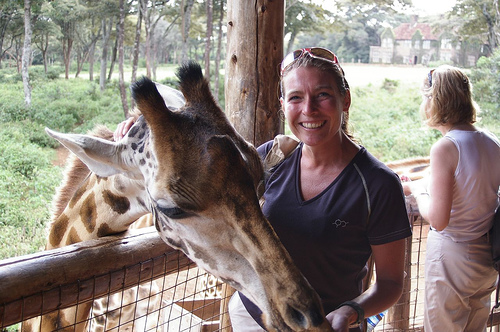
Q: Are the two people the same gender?
A: Yes, all the people are female.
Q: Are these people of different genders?
A: No, all the people are female.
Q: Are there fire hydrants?
A: No, there are no fire hydrants.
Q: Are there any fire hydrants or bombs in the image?
A: No, there are no fire hydrants or bombs.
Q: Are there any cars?
A: No, there are no cars.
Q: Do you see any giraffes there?
A: Yes, there is a giraffe.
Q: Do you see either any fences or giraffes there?
A: Yes, there is a giraffe.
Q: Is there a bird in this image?
A: No, there are no birds.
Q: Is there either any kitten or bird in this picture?
A: No, there are no birds or kittens.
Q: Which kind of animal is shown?
A: The animal is a giraffe.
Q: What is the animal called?
A: The animal is a giraffe.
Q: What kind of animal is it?
A: The animal is a giraffe.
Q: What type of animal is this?
A: This is a giraffe.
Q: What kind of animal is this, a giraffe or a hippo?
A: This is a giraffe.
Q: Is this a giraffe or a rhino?
A: This is a giraffe.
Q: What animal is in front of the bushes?
A: The giraffe is in front of the shrubs.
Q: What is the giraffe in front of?
A: The giraffe is in front of the bushes.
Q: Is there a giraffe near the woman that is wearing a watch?
A: Yes, there is a giraffe near the woman.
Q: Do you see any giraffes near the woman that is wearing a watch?
A: Yes, there is a giraffe near the woman.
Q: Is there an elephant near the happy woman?
A: No, there is a giraffe near the woman.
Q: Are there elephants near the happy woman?
A: No, there is a giraffe near the woman.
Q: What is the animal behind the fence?
A: The animal is a giraffe.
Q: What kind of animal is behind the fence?
A: The animal is a giraffe.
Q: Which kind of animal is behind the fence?
A: The animal is a giraffe.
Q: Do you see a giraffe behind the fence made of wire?
A: Yes, there is a giraffe behind the fence.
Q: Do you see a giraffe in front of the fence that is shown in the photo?
A: No, the giraffe is behind the fence.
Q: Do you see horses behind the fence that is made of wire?
A: No, there is a giraffe behind the fence.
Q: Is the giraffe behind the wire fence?
A: Yes, the giraffe is behind the fence.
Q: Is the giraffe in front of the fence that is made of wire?
A: No, the giraffe is behind the fence.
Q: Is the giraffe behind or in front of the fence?
A: The giraffe is behind the fence.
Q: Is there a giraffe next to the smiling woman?
A: Yes, there is a giraffe next to the woman.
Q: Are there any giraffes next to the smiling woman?
A: Yes, there is a giraffe next to the woman.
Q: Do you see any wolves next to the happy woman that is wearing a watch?
A: No, there is a giraffe next to the woman.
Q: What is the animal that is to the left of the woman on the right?
A: The animal is a giraffe.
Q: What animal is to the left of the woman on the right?
A: The animal is a giraffe.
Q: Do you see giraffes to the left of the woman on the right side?
A: Yes, there is a giraffe to the left of the woman.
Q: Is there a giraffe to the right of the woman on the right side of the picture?
A: No, the giraffe is to the left of the woman.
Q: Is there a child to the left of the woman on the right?
A: No, there is a giraffe to the left of the woman.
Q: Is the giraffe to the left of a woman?
A: Yes, the giraffe is to the left of a woman.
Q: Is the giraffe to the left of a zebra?
A: No, the giraffe is to the left of a woman.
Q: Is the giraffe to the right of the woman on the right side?
A: No, the giraffe is to the left of the woman.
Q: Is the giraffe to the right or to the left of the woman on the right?
A: The giraffe is to the left of the woman.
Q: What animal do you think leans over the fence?
A: The giraffe leans over the fence.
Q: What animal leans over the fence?
A: The giraffe leans over the fence.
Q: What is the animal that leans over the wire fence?
A: The animal is a giraffe.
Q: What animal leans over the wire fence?
A: The animal is a giraffe.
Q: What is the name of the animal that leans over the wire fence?
A: The animal is a giraffe.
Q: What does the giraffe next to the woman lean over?
A: The giraffe leans over the fence.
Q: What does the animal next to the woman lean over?
A: The giraffe leans over the fence.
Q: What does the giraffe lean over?
A: The giraffe leans over the fence.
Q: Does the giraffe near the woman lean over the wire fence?
A: Yes, the giraffe leans over the fence.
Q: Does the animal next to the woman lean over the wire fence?
A: Yes, the giraffe leans over the fence.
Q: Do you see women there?
A: Yes, there is a woman.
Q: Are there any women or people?
A: Yes, there is a woman.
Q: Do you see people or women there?
A: Yes, there is a woman.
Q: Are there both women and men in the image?
A: No, there is a woman but no men.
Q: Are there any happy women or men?
A: Yes, there is a happy woman.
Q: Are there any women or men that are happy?
A: Yes, the woman is happy.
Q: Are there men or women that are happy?
A: Yes, the woman is happy.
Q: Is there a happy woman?
A: Yes, there is a happy woman.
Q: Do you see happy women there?
A: Yes, there is a happy woman.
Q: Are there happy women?
A: Yes, there is a happy woman.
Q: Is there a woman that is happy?
A: Yes, there is a woman that is happy.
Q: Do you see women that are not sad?
A: Yes, there is a happy woman.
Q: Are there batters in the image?
A: No, there are no batters.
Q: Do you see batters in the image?
A: No, there are no batters.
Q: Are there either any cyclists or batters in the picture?
A: No, there are no batters or cyclists.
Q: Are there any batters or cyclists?
A: No, there are no batters or cyclists.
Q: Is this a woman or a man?
A: This is a woman.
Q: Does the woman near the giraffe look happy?
A: Yes, the woman is happy.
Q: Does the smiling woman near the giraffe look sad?
A: No, the woman is happy.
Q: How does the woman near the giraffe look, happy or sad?
A: The woman is happy.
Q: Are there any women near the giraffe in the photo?
A: Yes, there is a woman near the giraffe.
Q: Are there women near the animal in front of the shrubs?
A: Yes, there is a woman near the giraffe.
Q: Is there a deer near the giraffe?
A: No, there is a woman near the giraffe.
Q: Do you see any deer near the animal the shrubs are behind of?
A: No, there is a woman near the giraffe.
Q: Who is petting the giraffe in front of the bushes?
A: The woman is petting the giraffe.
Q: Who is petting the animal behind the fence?
A: The woman is petting the giraffe.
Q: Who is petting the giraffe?
A: The woman is petting the giraffe.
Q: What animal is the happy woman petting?
A: The woman is petting the giraffe.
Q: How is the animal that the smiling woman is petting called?
A: The animal is a giraffe.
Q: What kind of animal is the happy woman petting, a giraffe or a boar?
A: The woman is petting a giraffe.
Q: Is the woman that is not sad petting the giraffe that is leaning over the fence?
A: Yes, the woman is petting the giraffe.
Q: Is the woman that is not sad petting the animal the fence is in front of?
A: Yes, the woman is petting the giraffe.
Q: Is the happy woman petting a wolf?
A: No, the woman is petting the giraffe.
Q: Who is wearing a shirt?
A: The woman is wearing a shirt.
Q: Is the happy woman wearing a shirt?
A: Yes, the woman is wearing a shirt.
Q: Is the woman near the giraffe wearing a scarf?
A: No, the woman is wearing a shirt.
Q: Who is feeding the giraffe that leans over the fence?
A: The woman is feeding the giraffe.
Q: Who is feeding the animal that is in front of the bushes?
A: The woman is feeding the giraffe.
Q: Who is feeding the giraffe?
A: The woman is feeding the giraffe.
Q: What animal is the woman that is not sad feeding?
A: The woman is feeding the giraffe.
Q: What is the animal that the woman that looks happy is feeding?
A: The animal is a giraffe.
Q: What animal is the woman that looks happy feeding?
A: The woman is feeding the giraffe.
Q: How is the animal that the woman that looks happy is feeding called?
A: The animal is a giraffe.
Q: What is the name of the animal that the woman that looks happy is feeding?
A: The animal is a giraffe.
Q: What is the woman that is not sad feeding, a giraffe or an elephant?
A: The woman is feeding a giraffe.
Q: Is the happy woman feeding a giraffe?
A: Yes, the woman is feeding a giraffe.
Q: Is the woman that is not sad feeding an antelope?
A: No, the woman is feeding a giraffe.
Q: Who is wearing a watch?
A: The woman is wearing a watch.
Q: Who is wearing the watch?
A: The woman is wearing a watch.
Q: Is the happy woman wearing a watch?
A: Yes, the woman is wearing a watch.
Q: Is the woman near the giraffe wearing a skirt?
A: No, the woman is wearing a watch.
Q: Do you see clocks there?
A: No, there are no clocks.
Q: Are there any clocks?
A: No, there are no clocks.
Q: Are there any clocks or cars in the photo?
A: No, there are no clocks or cars.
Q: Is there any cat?
A: No, there are no cats.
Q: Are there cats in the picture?
A: No, there are no cats.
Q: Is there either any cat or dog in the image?
A: No, there are no cats or dogs.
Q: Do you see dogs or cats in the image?
A: No, there are no cats or dogs.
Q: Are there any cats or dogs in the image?
A: No, there are no cats or dogs.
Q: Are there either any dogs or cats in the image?
A: No, there are no cats or dogs.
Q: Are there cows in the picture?
A: No, there are no cows.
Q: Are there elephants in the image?
A: No, there are no elephants.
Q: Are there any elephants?
A: No, there are no elephants.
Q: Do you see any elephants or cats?
A: No, there are no elephants or cats.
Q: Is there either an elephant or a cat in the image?
A: No, there are no elephants or cats.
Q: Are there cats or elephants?
A: No, there are no elephants or cats.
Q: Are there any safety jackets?
A: No, there are no safety jackets.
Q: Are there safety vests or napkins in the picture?
A: No, there are no safety vests or napkins.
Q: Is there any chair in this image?
A: No, there are no chairs.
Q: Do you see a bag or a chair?
A: No, there are no chairs or bags.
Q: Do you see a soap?
A: No, there are no soaps.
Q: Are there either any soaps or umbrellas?
A: No, there are no soaps or umbrellas.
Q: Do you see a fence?
A: Yes, there is a fence.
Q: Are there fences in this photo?
A: Yes, there is a fence.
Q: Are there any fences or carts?
A: Yes, there is a fence.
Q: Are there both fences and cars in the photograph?
A: No, there is a fence but no cars.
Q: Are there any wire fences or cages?
A: Yes, there is a wire fence.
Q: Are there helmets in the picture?
A: No, there are no helmets.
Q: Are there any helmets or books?
A: No, there are no helmets or books.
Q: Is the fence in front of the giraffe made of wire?
A: Yes, the fence is made of wire.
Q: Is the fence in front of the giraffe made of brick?
A: No, the fence is made of wire.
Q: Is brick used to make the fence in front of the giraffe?
A: No, the fence is made of wire.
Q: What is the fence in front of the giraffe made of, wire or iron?
A: The fence is made of wire.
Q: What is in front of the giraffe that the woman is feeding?
A: The fence is in front of the giraffe.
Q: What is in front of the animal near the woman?
A: The fence is in front of the giraffe.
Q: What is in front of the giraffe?
A: The fence is in front of the giraffe.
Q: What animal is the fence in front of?
A: The fence is in front of the giraffe.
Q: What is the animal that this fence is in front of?
A: The animal is a giraffe.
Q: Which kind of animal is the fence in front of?
A: The fence is in front of the giraffe.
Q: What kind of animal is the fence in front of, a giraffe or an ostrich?
A: The fence is in front of a giraffe.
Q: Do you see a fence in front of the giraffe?
A: Yes, there is a fence in front of the giraffe.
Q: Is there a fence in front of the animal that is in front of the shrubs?
A: Yes, there is a fence in front of the giraffe.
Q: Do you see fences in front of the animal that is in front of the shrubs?
A: Yes, there is a fence in front of the giraffe.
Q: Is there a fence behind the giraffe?
A: No, the fence is in front of the giraffe.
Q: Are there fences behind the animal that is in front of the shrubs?
A: No, the fence is in front of the giraffe.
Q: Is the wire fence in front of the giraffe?
A: Yes, the fence is in front of the giraffe.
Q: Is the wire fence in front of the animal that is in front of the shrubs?
A: Yes, the fence is in front of the giraffe.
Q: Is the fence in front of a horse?
A: No, the fence is in front of the giraffe.